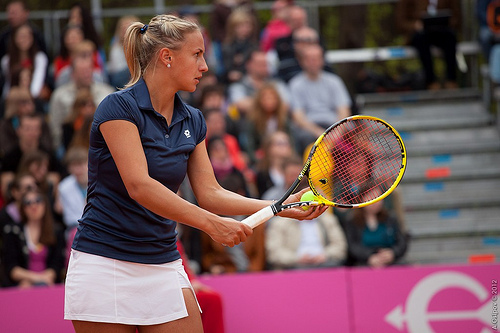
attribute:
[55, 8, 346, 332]
woman — blonde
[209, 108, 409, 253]
racket — yellow, black, white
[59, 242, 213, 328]
skirt — white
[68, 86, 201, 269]
shirt — blue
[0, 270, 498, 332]
wall — pink